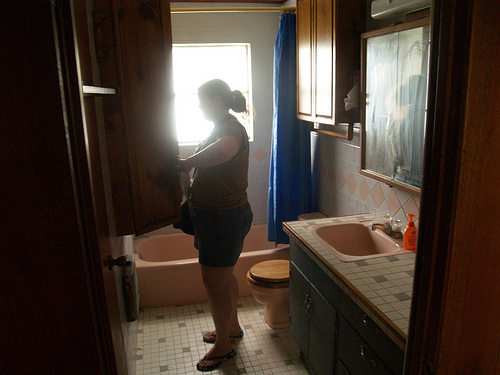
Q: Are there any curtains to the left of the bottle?
A: Yes, there is a curtain to the left of the bottle.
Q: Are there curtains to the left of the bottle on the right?
A: Yes, there is a curtain to the left of the bottle.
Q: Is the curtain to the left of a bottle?
A: Yes, the curtain is to the left of a bottle.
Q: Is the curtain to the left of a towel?
A: No, the curtain is to the left of a bottle.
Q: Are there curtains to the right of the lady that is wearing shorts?
A: Yes, there is a curtain to the right of the lady.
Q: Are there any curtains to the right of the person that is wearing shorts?
A: Yes, there is a curtain to the right of the lady.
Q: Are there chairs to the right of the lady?
A: No, there is a curtain to the right of the lady.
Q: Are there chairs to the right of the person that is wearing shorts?
A: No, there is a curtain to the right of the lady.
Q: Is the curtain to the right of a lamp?
A: No, the curtain is to the right of a lady.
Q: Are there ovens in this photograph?
A: No, there are no ovens.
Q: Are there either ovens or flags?
A: No, there are no ovens or flags.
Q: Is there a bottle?
A: Yes, there is a bottle.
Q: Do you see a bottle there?
A: Yes, there is a bottle.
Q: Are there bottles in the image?
A: Yes, there is a bottle.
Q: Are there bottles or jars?
A: Yes, there is a bottle.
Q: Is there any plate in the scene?
A: No, there are no plates.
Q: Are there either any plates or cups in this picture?
A: No, there are no plates or cups.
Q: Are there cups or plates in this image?
A: No, there are no plates or cups.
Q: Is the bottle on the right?
A: Yes, the bottle is on the right of the image.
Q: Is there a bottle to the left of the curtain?
A: No, the bottle is to the right of the curtain.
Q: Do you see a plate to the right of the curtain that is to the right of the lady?
A: No, there is a bottle to the right of the curtain.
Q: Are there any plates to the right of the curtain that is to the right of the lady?
A: No, there is a bottle to the right of the curtain.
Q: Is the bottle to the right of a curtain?
A: Yes, the bottle is to the right of a curtain.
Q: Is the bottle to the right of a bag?
A: No, the bottle is to the right of a curtain.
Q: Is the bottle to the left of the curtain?
A: No, the bottle is to the right of the curtain.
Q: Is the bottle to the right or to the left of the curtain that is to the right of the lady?
A: The bottle is to the right of the curtain.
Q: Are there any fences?
A: No, there are no fences.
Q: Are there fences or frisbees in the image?
A: No, there are no fences or frisbees.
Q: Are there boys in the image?
A: No, there are no boys.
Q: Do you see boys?
A: No, there are no boys.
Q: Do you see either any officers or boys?
A: No, there are no boys or officers.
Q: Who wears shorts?
A: The lady wears shorts.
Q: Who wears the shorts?
A: The lady wears shorts.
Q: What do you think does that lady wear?
A: The lady wears shorts.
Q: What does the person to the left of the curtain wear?
A: The lady wears shorts.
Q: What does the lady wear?
A: The lady wears shorts.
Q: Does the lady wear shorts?
A: Yes, the lady wears shorts.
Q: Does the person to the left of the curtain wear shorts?
A: Yes, the lady wears shorts.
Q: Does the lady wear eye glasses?
A: No, the lady wears shorts.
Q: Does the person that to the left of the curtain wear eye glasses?
A: No, the lady wears shorts.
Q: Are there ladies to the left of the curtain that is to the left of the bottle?
A: Yes, there is a lady to the left of the curtain.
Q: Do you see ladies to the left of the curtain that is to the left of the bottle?
A: Yes, there is a lady to the left of the curtain.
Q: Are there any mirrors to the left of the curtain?
A: No, there is a lady to the left of the curtain.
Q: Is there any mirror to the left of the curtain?
A: No, there is a lady to the left of the curtain.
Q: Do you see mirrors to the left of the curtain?
A: No, there is a lady to the left of the curtain.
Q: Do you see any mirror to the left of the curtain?
A: No, there is a lady to the left of the curtain.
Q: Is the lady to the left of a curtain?
A: Yes, the lady is to the left of a curtain.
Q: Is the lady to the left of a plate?
A: No, the lady is to the left of a curtain.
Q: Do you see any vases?
A: No, there are no vases.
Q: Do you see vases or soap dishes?
A: No, there are no vases or soap dishes.